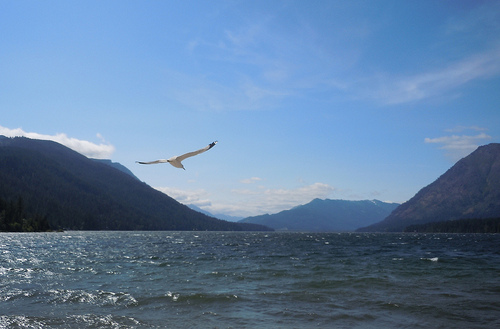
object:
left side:
[0, 229, 220, 329]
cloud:
[0, 126, 116, 159]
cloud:
[159, 8, 499, 113]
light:
[0, 231, 186, 329]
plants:
[0, 145, 173, 231]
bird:
[135, 139, 219, 170]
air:
[287, 24, 471, 133]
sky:
[0, 0, 499, 212]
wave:
[46, 287, 139, 307]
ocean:
[0, 229, 500, 329]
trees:
[0, 182, 500, 233]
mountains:
[0, 135, 500, 233]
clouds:
[153, 176, 408, 218]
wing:
[176, 140, 219, 161]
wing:
[135, 159, 168, 165]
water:
[0, 230, 500, 329]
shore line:
[64, 230, 500, 236]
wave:
[420, 257, 458, 263]